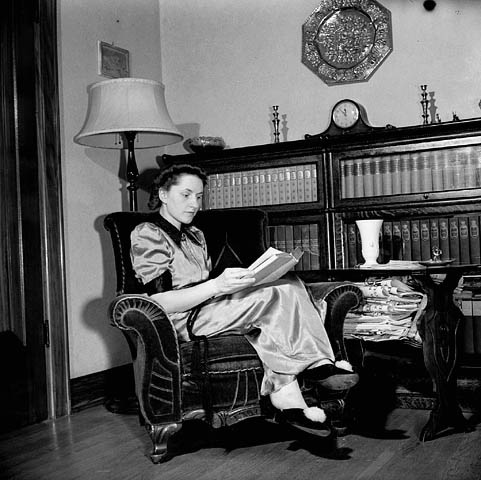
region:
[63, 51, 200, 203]
floor lamp behind a chair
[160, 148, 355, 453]
woman sitting in a black chair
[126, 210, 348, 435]
large black chair with a woman sitting in it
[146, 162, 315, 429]
woman reading a book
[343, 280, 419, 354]
new papers on a stand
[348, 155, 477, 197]
books on a shelf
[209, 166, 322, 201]
books on a shelf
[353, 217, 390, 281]
vase on table stand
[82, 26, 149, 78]
picture on a wall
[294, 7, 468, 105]
picture on a wall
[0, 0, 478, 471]
the picture is in black and white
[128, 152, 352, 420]
the woman is reading a book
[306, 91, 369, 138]
a clock is on the shelf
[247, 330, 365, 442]
the woman's shoes are black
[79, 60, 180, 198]
the lamp is behind the woman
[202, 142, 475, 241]
books are on the shelf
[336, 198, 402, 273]
a vase is on the desk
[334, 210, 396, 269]
the vase is white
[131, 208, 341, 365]
the woman is wearing a dress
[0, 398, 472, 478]
the floor is made from wood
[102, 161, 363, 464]
The woman is sitting in a chair.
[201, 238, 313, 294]
The woman is reading a book.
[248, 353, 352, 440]
The woman has shoes on her feet.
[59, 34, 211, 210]
A lamp is in the room.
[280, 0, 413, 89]
A decorative plate is hanging on the wall.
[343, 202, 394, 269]
A vase is on the table.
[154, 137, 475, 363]
A bookshelf is in the room.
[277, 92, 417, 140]
A clock is on top of the bookshelf.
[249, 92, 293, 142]
A candlestick on top of the bookshelf.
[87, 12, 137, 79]
A picture on the wall.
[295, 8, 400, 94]
octagonal copper wall plate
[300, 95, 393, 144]
mantle clock reading 11:54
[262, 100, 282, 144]
brass candlestick holder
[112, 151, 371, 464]
woman in velvet armchair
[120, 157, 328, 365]
woman reading a book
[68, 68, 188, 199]
lamp with white lampshade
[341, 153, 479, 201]
set of encyclopedias on the bookshelf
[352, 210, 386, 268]
empty white vase on shelf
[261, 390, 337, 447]
velvet slippers with pom poms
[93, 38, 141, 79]
small framed picture on the wall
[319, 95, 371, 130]
Clock on the bookshelf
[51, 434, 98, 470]
Floor made of wood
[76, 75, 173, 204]
Huge lamp in front of the wall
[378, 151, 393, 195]
On of the books on the bookshelf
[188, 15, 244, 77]
Small part of white wall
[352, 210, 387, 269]
White vase on desk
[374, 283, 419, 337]
Large stack of newspaper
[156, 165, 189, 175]
Black hair of lady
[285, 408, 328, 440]
Black and white shoes of the lady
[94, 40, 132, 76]
Square object on wall